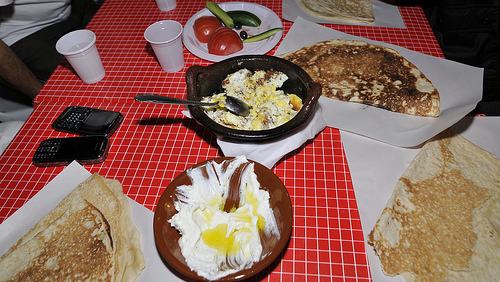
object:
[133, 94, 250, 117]
spoon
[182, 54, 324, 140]
skillet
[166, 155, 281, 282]
egg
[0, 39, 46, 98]
arm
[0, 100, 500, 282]
table cloth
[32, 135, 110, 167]
phones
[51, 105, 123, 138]
phones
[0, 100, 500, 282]
table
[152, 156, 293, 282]
plate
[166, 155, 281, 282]
dipping sauce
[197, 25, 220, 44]
tomato